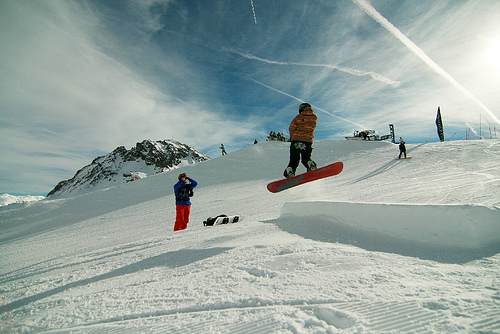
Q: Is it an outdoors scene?
A: Yes, it is outdoors.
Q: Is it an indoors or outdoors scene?
A: It is outdoors.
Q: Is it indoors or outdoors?
A: It is outdoors.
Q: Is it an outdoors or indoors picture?
A: It is outdoors.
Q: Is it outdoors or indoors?
A: It is outdoors.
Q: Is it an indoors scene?
A: No, it is outdoors.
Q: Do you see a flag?
A: Yes, there is a flag.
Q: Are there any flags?
A: Yes, there is a flag.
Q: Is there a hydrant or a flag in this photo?
A: Yes, there is a flag.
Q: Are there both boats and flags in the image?
A: No, there is a flag but no boats.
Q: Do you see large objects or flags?
A: Yes, there is a large flag.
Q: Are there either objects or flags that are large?
A: Yes, the flag is large.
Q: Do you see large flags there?
A: Yes, there is a large flag.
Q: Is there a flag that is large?
A: Yes, there is a flag that is large.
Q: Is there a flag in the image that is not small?
A: Yes, there is a large flag.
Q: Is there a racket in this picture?
A: No, there are no rackets.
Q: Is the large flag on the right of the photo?
A: Yes, the flag is on the right of the image.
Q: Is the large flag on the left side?
A: No, the flag is on the right of the image.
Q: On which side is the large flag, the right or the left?
A: The flag is on the right of the image.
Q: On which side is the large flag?
A: The flag is on the right of the image.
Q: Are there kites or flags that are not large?
A: No, there is a flag but it is large.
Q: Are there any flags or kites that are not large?
A: No, there is a flag but it is large.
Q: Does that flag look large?
A: Yes, the flag is large.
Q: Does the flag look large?
A: Yes, the flag is large.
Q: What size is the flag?
A: The flag is large.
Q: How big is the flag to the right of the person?
A: The flag is large.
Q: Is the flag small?
A: No, the flag is large.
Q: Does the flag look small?
A: No, the flag is large.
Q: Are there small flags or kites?
A: No, there is a flag but it is large.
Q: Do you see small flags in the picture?
A: No, there is a flag but it is large.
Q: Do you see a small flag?
A: No, there is a flag but it is large.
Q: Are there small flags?
A: No, there is a flag but it is large.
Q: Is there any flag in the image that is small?
A: No, there is a flag but it is large.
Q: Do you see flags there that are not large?
A: No, there is a flag but it is large.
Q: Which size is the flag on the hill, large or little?
A: The flag is large.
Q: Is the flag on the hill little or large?
A: The flag is large.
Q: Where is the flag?
A: The flag is on the hill.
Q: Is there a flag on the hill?
A: Yes, there is a flag on the hill.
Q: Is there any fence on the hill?
A: No, there is a flag on the hill.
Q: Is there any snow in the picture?
A: Yes, there is snow.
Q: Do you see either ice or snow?
A: Yes, there is snow.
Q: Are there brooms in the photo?
A: No, there are no brooms.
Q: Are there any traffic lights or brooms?
A: No, there are no brooms or traffic lights.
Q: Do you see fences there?
A: No, there are no fences.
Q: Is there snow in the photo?
A: Yes, there is snow.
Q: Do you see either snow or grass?
A: Yes, there is snow.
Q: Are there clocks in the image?
A: No, there are no clocks.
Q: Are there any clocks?
A: No, there are no clocks.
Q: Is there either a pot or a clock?
A: No, there are no clocks or pots.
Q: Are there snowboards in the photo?
A: Yes, there is a snowboard.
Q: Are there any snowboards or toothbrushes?
A: Yes, there is a snowboard.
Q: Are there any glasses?
A: No, there are no glasses.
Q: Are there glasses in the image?
A: No, there are no glasses.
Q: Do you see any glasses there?
A: No, there are no glasses.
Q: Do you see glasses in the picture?
A: No, there are no glasses.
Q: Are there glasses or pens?
A: No, there are no glasses or pens.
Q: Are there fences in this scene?
A: No, there are no fences.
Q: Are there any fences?
A: No, there are no fences.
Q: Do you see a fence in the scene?
A: No, there are no fences.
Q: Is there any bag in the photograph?
A: Yes, there is a bag.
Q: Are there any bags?
A: Yes, there is a bag.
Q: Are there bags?
A: Yes, there is a bag.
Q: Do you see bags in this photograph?
A: Yes, there is a bag.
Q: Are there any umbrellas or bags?
A: Yes, there is a bag.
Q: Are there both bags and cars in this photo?
A: No, there is a bag but no cars.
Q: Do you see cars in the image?
A: No, there are no cars.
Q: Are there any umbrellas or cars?
A: No, there are no cars or umbrellas.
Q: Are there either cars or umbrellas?
A: No, there are no cars or umbrellas.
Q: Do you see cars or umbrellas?
A: No, there are no cars or umbrellas.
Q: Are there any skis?
A: No, there are no skis.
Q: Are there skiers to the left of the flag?
A: Yes, there is a skier to the left of the flag.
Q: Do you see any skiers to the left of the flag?
A: Yes, there is a skier to the left of the flag.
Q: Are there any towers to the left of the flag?
A: No, there is a skier to the left of the flag.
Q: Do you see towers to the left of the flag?
A: No, there is a skier to the left of the flag.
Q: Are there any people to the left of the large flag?
A: Yes, there is a person to the left of the flag.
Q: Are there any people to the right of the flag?
A: No, the person is to the left of the flag.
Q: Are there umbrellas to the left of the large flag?
A: No, there is a person to the left of the flag.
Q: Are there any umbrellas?
A: No, there are no umbrellas.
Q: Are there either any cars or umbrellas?
A: No, there are no umbrellas or cars.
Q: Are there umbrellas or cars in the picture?
A: No, there are no umbrellas or cars.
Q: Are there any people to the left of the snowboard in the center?
A: Yes, there are people to the left of the snow board.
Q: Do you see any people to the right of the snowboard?
A: No, the people are to the left of the snowboard.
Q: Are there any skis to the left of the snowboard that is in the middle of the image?
A: No, there are people to the left of the snowboard.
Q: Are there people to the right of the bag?
A: No, the people are to the left of the bag.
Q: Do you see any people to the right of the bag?
A: No, the people are to the left of the bag.